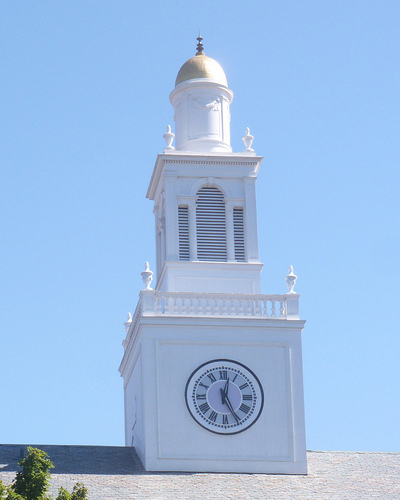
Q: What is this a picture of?
A: Steeple.